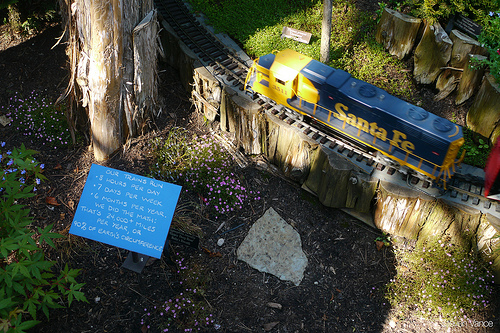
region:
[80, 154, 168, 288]
words are written on a blue paper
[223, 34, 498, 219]
the train is moving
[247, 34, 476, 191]
the train is yellow and blue in color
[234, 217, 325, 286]
the rock is liying on the floor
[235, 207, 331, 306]
rock is grey in color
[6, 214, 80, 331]
plants are green in color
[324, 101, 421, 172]
the words are written in yellow color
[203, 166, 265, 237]
the flower petals are purple in color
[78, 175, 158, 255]
words are written in white color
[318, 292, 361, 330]
the floor is black in color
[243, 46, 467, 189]
A model train.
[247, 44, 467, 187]
A model train that says Santa Fe.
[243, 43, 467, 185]
A navy blue and yellow model train.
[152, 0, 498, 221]
A model train track.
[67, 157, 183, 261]
A sign with information about the trains.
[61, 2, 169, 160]
A tree trunk.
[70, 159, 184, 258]
A blue sign with white lettering.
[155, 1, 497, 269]
A train track raised by some wooden stumps.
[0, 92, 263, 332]
Some small purple flowers.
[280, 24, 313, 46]
A small sign.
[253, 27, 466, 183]
train on a track exhibit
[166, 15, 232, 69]
track train is on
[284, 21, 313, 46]
card explaining the exhibit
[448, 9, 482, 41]
card explaining the exhibit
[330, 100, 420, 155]
letters on the train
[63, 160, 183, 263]
plaque explaining the exhibit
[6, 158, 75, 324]
plants on the ground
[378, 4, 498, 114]
bark on the exhibit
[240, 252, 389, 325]
dirt on the ground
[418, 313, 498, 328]
credit to the artist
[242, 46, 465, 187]
a yellow and blue model train engine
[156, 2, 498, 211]
model train tracks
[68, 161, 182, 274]
a small handwritten sign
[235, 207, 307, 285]
a small flat stone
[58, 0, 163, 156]
a small tree stump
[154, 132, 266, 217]
a patch of pink flowers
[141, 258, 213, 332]
a patch of pink flowers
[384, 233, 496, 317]
a patch of pink flowers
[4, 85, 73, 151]
a patch of pink flowers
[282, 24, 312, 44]
a small informational sign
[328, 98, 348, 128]
The letter is yellow.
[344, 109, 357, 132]
The letter is yellow.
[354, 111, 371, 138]
The letter is yellow.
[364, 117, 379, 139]
The letter is yellow.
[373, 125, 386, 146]
The letter is yellow.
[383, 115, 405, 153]
The letter is yellow.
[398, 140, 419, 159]
The letter is yellow.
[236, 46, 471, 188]
The train is blue and yellow.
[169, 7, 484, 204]
The train is on a track.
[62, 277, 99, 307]
The leaf is green.